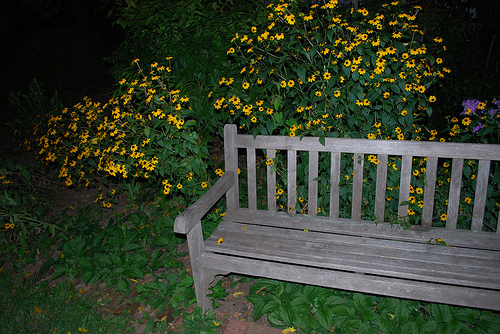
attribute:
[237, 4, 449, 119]
bush — yellow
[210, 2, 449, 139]
flowers — yellow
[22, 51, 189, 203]
flowers — yellow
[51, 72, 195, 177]
flowers — yellow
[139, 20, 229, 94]
bush — green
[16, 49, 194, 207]
daisies — black, yellow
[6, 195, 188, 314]
leaves — green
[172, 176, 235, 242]
rest — arm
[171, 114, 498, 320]
bench — wooden back, wooden seat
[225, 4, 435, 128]
bush — black, yellow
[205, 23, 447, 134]
flowers — yellow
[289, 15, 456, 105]
flowers — yellow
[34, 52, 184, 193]
flowers — yellow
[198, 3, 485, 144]
flower bush — flower bush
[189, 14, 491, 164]
bush — purple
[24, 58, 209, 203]
flowers — yellow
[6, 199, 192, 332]
green shrubs — small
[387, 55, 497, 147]
flowers — purple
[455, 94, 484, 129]
flowers — purple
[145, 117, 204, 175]
leaves — green